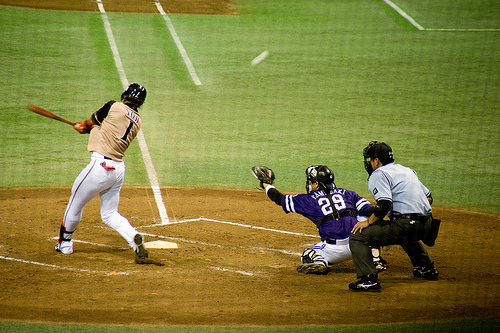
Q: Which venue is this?
A: This is a field.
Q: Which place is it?
A: It is a field.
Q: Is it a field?
A: Yes, it is a field.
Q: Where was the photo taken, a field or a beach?
A: It was taken at a field.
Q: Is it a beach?
A: No, it is a field.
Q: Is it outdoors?
A: Yes, it is outdoors.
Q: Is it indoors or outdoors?
A: It is outdoors.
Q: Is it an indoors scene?
A: No, it is outdoors.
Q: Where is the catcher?
A: The catcher is on the field.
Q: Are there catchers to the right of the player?
A: Yes, there is a catcher to the right of the player.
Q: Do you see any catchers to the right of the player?
A: Yes, there is a catcher to the right of the player.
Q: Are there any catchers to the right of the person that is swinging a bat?
A: Yes, there is a catcher to the right of the player.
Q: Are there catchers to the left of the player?
A: No, the catcher is to the right of the player.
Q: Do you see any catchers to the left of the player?
A: No, the catcher is to the right of the player.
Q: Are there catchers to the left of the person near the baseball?
A: No, the catcher is to the right of the player.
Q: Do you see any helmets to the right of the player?
A: No, there is a catcher to the right of the player.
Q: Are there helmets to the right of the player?
A: No, there is a catcher to the right of the player.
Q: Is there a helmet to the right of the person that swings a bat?
A: No, there is a catcher to the right of the player.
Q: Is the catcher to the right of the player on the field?
A: Yes, the catcher is to the right of the player.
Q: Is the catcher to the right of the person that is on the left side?
A: Yes, the catcher is to the right of the player.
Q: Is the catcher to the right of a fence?
A: No, the catcher is to the right of the player.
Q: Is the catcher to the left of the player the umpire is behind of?
A: No, the catcher is to the right of the player.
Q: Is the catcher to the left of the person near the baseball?
A: No, the catcher is to the right of the player.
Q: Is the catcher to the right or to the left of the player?
A: The catcher is to the right of the player.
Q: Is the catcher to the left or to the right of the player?
A: The catcher is to the right of the player.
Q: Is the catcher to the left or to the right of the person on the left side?
A: The catcher is to the right of the player.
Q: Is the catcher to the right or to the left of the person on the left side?
A: The catcher is to the right of the player.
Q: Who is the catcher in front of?
A: The catcher is in front of the umpire.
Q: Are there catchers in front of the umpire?
A: Yes, there is a catcher in front of the umpire.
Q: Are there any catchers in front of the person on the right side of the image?
A: Yes, there is a catcher in front of the umpire.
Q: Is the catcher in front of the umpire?
A: Yes, the catcher is in front of the umpire.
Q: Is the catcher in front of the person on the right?
A: Yes, the catcher is in front of the umpire.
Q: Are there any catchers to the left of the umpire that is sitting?
A: Yes, there is a catcher to the left of the umpire.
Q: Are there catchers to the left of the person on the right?
A: Yes, there is a catcher to the left of the umpire.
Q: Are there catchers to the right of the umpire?
A: No, the catcher is to the left of the umpire.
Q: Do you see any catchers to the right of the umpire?
A: No, the catcher is to the left of the umpire.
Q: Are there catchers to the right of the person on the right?
A: No, the catcher is to the left of the umpire.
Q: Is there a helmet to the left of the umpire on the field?
A: No, there is a catcher to the left of the umpire.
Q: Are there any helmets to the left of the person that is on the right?
A: No, there is a catcher to the left of the umpire.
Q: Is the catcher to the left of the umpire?
A: Yes, the catcher is to the left of the umpire.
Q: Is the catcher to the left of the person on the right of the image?
A: Yes, the catcher is to the left of the umpire.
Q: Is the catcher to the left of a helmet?
A: No, the catcher is to the left of the umpire.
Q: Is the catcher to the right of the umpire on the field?
A: No, the catcher is to the left of the umpire.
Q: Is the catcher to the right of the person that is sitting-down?
A: No, the catcher is to the left of the umpire.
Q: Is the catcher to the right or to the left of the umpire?
A: The catcher is to the left of the umpire.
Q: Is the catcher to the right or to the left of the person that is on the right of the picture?
A: The catcher is to the left of the umpire.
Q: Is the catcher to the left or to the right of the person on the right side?
A: The catcher is to the left of the umpire.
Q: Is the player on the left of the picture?
A: Yes, the player is on the left of the image.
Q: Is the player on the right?
A: No, the player is on the left of the image.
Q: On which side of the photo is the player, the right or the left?
A: The player is on the left of the image.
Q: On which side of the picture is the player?
A: The player is on the left of the image.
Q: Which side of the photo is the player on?
A: The player is on the left of the image.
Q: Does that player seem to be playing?
A: Yes, the player is playing.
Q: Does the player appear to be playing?
A: Yes, the player is playing.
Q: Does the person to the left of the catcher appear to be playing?
A: Yes, the player is playing.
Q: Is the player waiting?
A: No, the player is playing.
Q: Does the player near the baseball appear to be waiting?
A: No, the player is playing.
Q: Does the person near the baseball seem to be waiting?
A: No, the player is playing.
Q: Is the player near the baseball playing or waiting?
A: The player is playing.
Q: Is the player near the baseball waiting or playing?
A: The player is playing.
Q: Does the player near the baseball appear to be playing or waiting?
A: The player is playing.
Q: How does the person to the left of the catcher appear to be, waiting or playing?
A: The player is playing.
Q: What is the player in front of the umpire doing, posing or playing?
A: The player is playing.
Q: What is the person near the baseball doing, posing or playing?
A: The player is playing.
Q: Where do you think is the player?
A: The player is on the field.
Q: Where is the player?
A: The player is on the field.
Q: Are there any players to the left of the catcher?
A: Yes, there is a player to the left of the catcher.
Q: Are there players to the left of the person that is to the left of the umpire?
A: Yes, there is a player to the left of the catcher.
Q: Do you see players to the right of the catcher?
A: No, the player is to the left of the catcher.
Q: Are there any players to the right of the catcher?
A: No, the player is to the left of the catcher.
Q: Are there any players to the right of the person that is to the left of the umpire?
A: No, the player is to the left of the catcher.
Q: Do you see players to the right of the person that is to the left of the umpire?
A: No, the player is to the left of the catcher.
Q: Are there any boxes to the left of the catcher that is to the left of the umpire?
A: No, there is a player to the left of the catcher.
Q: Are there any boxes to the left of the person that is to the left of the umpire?
A: No, there is a player to the left of the catcher.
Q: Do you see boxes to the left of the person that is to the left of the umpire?
A: No, there is a player to the left of the catcher.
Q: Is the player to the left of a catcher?
A: Yes, the player is to the left of a catcher.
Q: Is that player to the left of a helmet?
A: No, the player is to the left of a catcher.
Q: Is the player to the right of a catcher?
A: No, the player is to the left of a catcher.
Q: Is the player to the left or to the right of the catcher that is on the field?
A: The player is to the left of the catcher.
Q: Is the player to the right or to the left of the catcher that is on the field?
A: The player is to the left of the catcher.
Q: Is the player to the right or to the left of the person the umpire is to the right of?
A: The player is to the left of the catcher.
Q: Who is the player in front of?
A: The player is in front of the umpire.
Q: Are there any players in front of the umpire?
A: Yes, there is a player in front of the umpire.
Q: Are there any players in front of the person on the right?
A: Yes, there is a player in front of the umpire.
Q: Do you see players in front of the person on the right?
A: Yes, there is a player in front of the umpire.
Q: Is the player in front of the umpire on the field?
A: Yes, the player is in front of the umpire.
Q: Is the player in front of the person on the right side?
A: Yes, the player is in front of the umpire.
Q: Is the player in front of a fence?
A: No, the player is in front of the umpire.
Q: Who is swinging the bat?
A: The player is swinging the bat.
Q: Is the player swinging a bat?
A: Yes, the player is swinging a bat.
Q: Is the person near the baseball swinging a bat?
A: Yes, the player is swinging a bat.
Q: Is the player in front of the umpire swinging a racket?
A: No, the player is swinging a bat.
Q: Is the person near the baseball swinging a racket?
A: No, the player is swinging a bat.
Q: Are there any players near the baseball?
A: Yes, there is a player near the baseball.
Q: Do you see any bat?
A: Yes, there is a bat.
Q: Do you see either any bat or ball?
A: Yes, there is a bat.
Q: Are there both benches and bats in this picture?
A: No, there is a bat but no benches.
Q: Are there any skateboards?
A: No, there are no skateboards.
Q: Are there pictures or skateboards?
A: No, there are no skateboards or pictures.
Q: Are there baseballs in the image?
A: Yes, there is a baseball.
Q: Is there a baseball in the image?
A: Yes, there is a baseball.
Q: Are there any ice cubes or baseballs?
A: Yes, there is a baseball.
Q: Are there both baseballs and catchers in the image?
A: Yes, there are both a baseball and a catcher.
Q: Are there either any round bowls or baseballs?
A: Yes, there is a round baseball.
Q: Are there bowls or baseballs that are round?
A: Yes, the baseball is round.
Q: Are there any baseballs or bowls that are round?
A: Yes, the baseball is round.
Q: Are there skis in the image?
A: No, there are no skis.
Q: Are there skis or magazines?
A: No, there are no skis or magazines.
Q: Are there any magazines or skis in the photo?
A: No, there are no skis or magazines.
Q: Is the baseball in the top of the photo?
A: Yes, the baseball is in the top of the image.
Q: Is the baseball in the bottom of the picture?
A: No, the baseball is in the top of the image.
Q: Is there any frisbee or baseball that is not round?
A: No, there is a baseball but it is round.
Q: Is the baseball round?
A: Yes, the baseball is round.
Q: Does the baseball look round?
A: Yes, the baseball is round.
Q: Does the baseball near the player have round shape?
A: Yes, the baseball is round.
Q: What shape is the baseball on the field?
A: The baseball is round.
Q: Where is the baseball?
A: The baseball is on the field.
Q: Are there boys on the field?
A: No, there is a baseball on the field.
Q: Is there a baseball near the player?
A: Yes, there is a baseball near the player.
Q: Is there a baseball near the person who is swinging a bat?
A: Yes, there is a baseball near the player.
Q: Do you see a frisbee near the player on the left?
A: No, there is a baseball near the player.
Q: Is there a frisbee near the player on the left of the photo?
A: No, there is a baseball near the player.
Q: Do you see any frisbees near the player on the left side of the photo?
A: No, there is a baseball near the player.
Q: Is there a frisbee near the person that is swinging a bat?
A: No, there is a baseball near the player.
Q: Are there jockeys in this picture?
A: No, there are no jockeys.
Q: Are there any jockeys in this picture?
A: No, there are no jockeys.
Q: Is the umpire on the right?
A: Yes, the umpire is on the right of the image.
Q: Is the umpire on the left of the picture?
A: No, the umpire is on the right of the image.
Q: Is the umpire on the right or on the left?
A: The umpire is on the right of the image.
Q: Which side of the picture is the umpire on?
A: The umpire is on the right of the image.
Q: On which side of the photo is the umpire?
A: The umpire is on the right of the image.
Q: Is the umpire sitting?
A: Yes, the umpire is sitting.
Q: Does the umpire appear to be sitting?
A: Yes, the umpire is sitting.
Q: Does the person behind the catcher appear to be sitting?
A: Yes, the umpire is sitting.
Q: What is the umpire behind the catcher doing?
A: The umpire is sitting.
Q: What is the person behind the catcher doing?
A: The umpire is sitting.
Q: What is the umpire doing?
A: The umpire is sitting.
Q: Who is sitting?
A: The umpire is sitting.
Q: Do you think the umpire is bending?
A: No, the umpire is sitting.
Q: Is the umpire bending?
A: No, the umpire is sitting.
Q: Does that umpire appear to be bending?
A: No, the umpire is sitting.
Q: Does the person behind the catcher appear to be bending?
A: No, the umpire is sitting.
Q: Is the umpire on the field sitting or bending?
A: The umpire is sitting.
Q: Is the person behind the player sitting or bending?
A: The umpire is sitting.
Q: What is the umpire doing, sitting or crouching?
A: The umpire is sitting.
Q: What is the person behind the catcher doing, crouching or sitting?
A: The umpire is sitting.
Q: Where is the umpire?
A: The umpire is on the field.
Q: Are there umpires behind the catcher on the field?
A: Yes, there is an umpire behind the catcher.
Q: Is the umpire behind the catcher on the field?
A: Yes, the umpire is behind the catcher.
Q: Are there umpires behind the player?
A: Yes, there is an umpire behind the player.